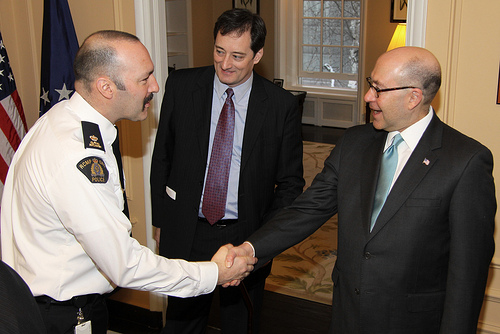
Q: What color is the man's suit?
A: Black.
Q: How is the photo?
A: Clear.